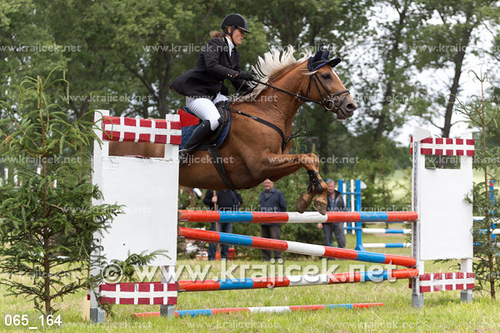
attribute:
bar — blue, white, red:
[178, 208, 416, 223]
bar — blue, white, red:
[177, 224, 417, 266]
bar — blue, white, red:
[179, 265, 417, 292]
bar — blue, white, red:
[130, 301, 395, 320]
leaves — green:
[1, 64, 172, 299]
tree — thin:
[0, 65, 169, 320]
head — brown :
[278, 19, 375, 129]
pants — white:
[184, 90, 229, 130]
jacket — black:
[178, 31, 246, 96]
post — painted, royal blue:
[348, 176, 365, 264]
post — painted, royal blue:
[180, 197, 417, 238]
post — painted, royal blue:
[181, 217, 444, 279]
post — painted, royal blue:
[179, 269, 441, 304]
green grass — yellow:
[346, 276, 429, 320]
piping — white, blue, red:
[183, 201, 418, 313]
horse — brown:
[171, 49, 343, 207]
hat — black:
[211, 10, 254, 42]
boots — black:
[181, 117, 221, 166]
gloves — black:
[235, 66, 258, 89]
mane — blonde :
[202, 62, 309, 111]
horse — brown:
[104, 48, 351, 229]